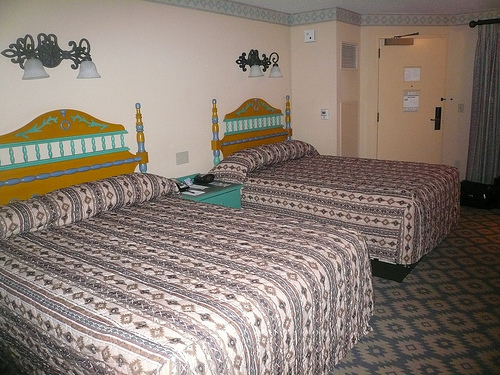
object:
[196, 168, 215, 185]
clock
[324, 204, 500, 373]
carpet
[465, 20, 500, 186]
curtains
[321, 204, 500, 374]
floor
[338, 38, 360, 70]
vent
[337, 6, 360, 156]
wall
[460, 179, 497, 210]
suitcase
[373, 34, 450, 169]
door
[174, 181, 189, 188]
phone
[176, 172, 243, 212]
desk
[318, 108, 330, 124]
thermostat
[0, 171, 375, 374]
bed spread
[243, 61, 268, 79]
lights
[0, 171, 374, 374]
comforter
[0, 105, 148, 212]
headboard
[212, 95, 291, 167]
headboard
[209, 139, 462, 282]
bed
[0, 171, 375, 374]
bed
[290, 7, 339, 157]
wall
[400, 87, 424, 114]
notice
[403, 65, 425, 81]
notice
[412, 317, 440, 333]
pattern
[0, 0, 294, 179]
wall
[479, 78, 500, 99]
window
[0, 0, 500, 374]
room